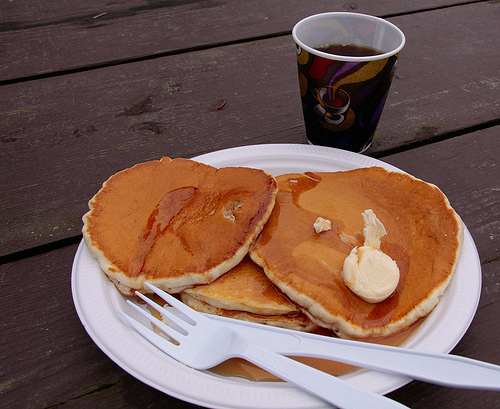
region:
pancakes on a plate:
[64, 136, 491, 407]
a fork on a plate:
[121, 284, 426, 406]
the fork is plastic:
[120, 274, 401, 405]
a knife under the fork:
[159, 294, 495, 384]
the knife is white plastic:
[156, 294, 491, 386]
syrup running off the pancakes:
[115, 159, 414, 329]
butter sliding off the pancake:
[300, 204, 412, 301]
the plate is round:
[67, 138, 484, 406]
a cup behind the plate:
[290, 7, 406, 158]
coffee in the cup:
[308, 33, 388, 63]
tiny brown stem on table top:
[203, 89, 230, 106]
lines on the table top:
[83, 29, 252, 54]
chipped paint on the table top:
[431, 81, 471, 99]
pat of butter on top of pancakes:
[337, 240, 406, 295]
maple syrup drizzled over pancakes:
[133, 180, 202, 240]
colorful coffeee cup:
[257, 7, 418, 142]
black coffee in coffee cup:
[308, 40, 395, 85]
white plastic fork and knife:
[132, 285, 354, 395]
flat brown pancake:
[58, 154, 295, 286]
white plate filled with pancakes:
[63, 158, 479, 396]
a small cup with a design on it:
[290, 11, 407, 153]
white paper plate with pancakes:
[67, 142, 484, 407]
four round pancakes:
[64, 151, 464, 333]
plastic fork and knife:
[119, 278, 499, 405]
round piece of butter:
[335, 237, 405, 304]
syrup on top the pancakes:
[87, 153, 455, 378]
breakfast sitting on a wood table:
[2, 7, 494, 406]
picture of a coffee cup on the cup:
[288, 12, 407, 152]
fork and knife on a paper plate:
[77, 239, 497, 406]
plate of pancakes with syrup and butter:
[67, 141, 483, 402]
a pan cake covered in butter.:
[253, 138, 469, 337]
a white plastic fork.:
[109, 274, 413, 407]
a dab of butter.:
[338, 245, 412, 305]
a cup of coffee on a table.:
[273, 8, 413, 152]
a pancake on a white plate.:
[78, 125, 293, 292]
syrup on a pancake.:
[107, 163, 244, 305]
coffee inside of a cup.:
[301, 30, 393, 59]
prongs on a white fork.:
[93, 252, 201, 345]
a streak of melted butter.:
[343, 200, 387, 254]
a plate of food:
[63, 130, 485, 379]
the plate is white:
[66, 115, 458, 390]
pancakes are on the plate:
[71, 139, 451, 350]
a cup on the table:
[272, 7, 413, 157]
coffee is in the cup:
[266, 4, 414, 151]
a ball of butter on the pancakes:
[285, 175, 406, 314]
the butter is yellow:
[305, 203, 406, 312]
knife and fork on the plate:
[107, 274, 474, 401]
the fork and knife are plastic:
[112, 272, 429, 404]